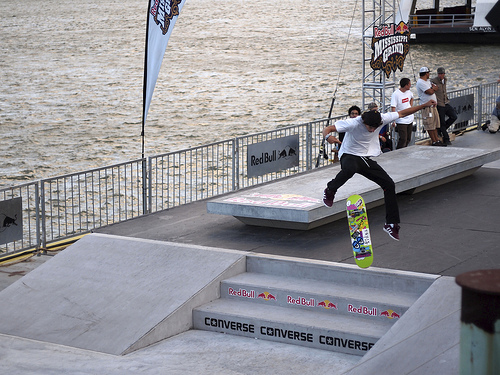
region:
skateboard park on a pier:
[8, 108, 492, 363]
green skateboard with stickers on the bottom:
[344, 190, 379, 267]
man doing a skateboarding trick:
[306, 88, 441, 263]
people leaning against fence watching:
[325, 54, 461, 153]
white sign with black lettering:
[235, 128, 307, 183]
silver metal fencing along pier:
[10, 60, 487, 253]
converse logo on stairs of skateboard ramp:
[192, 308, 379, 356]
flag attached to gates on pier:
[137, 0, 187, 202]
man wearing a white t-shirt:
[322, 96, 437, 170]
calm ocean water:
[35, 0, 291, 170]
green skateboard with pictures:
[346, 191, 373, 266]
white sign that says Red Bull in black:
[246, 133, 298, 175]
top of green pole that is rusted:
[454, 268, 498, 371]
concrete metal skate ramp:
[1, 230, 246, 355]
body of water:
[3, 2, 493, 248]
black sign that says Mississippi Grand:
[371, 20, 411, 77]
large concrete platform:
[206, 140, 498, 231]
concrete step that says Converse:
[194, 299, 391, 354]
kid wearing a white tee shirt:
[320, 100, 437, 242]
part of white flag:
[146, 0, 183, 128]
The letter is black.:
[203, 313, 213, 328]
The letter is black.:
[216, 317, 226, 334]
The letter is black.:
[222, 316, 232, 333]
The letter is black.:
[228, 317, 238, 333]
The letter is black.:
[234, 319, 243, 332]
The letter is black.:
[240, 322, 250, 334]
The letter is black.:
[247, 319, 257, 336]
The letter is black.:
[305, 330, 315, 344]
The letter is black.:
[298, 328, 308, 345]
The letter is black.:
[291, 326, 301, 345]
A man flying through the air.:
[314, 96, 438, 251]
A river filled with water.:
[0, 0, 400, 261]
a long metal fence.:
[0, 78, 497, 261]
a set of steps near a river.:
[128, 250, 453, 371]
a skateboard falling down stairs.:
[335, 183, 380, 276]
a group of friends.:
[383, 52, 466, 162]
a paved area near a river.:
[90, 130, 497, 291]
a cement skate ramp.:
[0, 227, 240, 372]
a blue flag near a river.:
[138, 0, 190, 162]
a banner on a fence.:
[235, 118, 312, 193]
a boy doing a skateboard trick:
[317, 101, 405, 273]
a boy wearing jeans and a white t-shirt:
[317, 107, 408, 242]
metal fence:
[2, 119, 334, 261]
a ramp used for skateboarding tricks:
[4, 231, 241, 351]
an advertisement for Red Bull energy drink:
[244, 132, 304, 182]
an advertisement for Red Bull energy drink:
[224, 284, 283, 301]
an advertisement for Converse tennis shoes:
[200, 314, 257, 334]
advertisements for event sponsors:
[198, 287, 423, 353]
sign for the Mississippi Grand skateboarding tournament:
[367, 19, 413, 79]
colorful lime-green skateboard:
[340, 189, 378, 274]